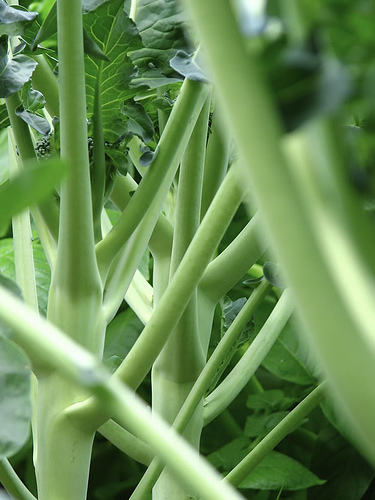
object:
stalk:
[155, 89, 211, 384]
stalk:
[94, 45, 213, 322]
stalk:
[5, 91, 61, 248]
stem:
[208, 211, 273, 299]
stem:
[4, 93, 58, 272]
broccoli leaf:
[125, 0, 194, 92]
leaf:
[81, 0, 151, 145]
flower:
[88, 140, 93, 151]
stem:
[0, 287, 245, 498]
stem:
[189, 0, 375, 468]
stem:
[146, 254, 221, 498]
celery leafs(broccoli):
[204, 436, 328, 490]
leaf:
[167, 50, 213, 86]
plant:
[180, 1, 375, 469]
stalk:
[204, 286, 296, 428]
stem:
[222, 378, 326, 486]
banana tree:
[0, 0, 374, 499]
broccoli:
[34, 131, 129, 201]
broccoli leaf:
[0, 0, 41, 42]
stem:
[28, 293, 108, 499]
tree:
[28, 0, 294, 498]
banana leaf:
[13, 81, 51, 137]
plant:
[0, 0, 249, 498]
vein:
[102, 96, 121, 106]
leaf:
[0, 33, 37, 98]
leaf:
[221, 446, 327, 491]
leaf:
[247, 302, 317, 387]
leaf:
[245, 387, 287, 412]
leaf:
[243, 405, 293, 446]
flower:
[36, 144, 45, 155]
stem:
[51, 0, 104, 298]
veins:
[101, 48, 129, 74]